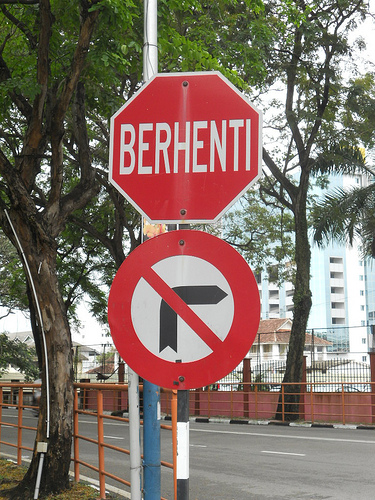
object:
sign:
[107, 229, 259, 391]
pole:
[143, 0, 161, 499]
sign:
[108, 71, 262, 225]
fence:
[0, 382, 178, 500]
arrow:
[159, 285, 229, 353]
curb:
[0, 382, 375, 427]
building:
[218, 163, 372, 364]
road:
[2, 409, 374, 498]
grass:
[0, 453, 127, 500]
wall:
[82, 384, 373, 424]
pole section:
[140, 380, 161, 499]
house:
[236, 318, 333, 376]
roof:
[253, 318, 333, 345]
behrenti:
[119, 119, 252, 176]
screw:
[183, 81, 189, 87]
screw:
[179, 239, 185, 247]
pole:
[176, 390, 189, 500]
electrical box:
[37, 441, 48, 452]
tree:
[0, 0, 293, 499]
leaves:
[339, 70, 375, 149]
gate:
[0, 379, 179, 500]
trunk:
[10, 242, 77, 482]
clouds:
[0, 1, 375, 355]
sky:
[0, 1, 373, 352]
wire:
[2, 208, 51, 498]